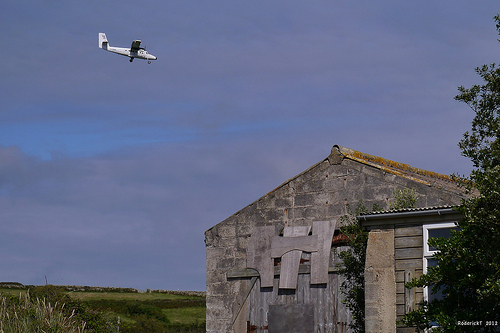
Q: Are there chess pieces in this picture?
A: No, there are no chess pieces.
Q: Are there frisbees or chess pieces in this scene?
A: No, there are no chess pieces or frisbees.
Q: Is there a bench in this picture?
A: No, there are no benches.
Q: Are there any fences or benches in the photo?
A: No, there are no benches or fences.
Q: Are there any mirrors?
A: No, there are no mirrors.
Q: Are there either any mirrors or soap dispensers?
A: No, there are no mirrors or soap dispensers.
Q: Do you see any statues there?
A: No, there are no statues.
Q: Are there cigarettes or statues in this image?
A: No, there are no statues or cigarettes.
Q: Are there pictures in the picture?
A: No, there are no pictures.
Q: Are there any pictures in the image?
A: No, there are no pictures.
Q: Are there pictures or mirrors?
A: No, there are no pictures or mirrors.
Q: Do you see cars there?
A: No, there are no cars.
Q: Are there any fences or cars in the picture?
A: No, there are no cars or fences.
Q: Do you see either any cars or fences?
A: No, there are no cars or fences.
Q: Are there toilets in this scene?
A: No, there are no toilets.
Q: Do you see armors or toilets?
A: No, there are no toilets or armors.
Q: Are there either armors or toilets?
A: No, there are no toilets or armors.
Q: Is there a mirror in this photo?
A: No, there are no mirrors.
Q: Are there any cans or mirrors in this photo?
A: No, there are no mirrors or cans.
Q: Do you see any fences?
A: No, there are no fences.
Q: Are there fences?
A: No, there are no fences.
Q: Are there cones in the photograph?
A: No, there are no cones.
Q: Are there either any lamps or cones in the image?
A: No, there are no cones or lamps.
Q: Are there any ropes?
A: No, there are no ropes.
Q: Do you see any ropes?
A: No, there are no ropes.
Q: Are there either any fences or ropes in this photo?
A: No, there are no ropes or fences.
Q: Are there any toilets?
A: No, there are no toilets.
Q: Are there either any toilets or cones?
A: No, there are no toilets or cones.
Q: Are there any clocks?
A: No, there are no clocks.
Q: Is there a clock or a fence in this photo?
A: No, there are no clocks or fences.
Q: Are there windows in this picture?
A: Yes, there is a window.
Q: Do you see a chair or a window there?
A: Yes, there is a window.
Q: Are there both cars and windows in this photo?
A: No, there is a window but no cars.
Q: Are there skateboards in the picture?
A: No, there are no skateboards.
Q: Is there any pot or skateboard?
A: No, there are no skateboards or pots.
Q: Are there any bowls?
A: No, there are no bowls.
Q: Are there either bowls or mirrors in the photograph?
A: No, there are no bowls or mirrors.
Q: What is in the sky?
A: The clouds are in the sky.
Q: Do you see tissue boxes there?
A: No, there are no tissue boxes.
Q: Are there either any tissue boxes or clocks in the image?
A: No, there are no tissue boxes or clocks.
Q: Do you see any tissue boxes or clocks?
A: No, there are no tissue boxes or clocks.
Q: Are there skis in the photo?
A: No, there are no skis.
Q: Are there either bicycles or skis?
A: No, there are no skis or bicycles.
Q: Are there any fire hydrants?
A: No, there are no fire hydrants.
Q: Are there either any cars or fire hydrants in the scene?
A: No, there are no fire hydrants or cars.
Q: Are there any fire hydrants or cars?
A: No, there are no fire hydrants or cars.